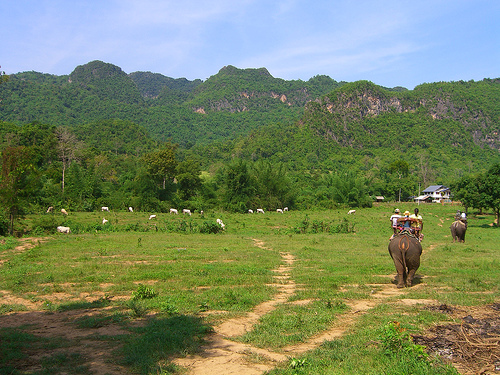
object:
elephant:
[388, 233, 423, 287]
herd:
[54, 226, 70, 234]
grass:
[2, 200, 500, 373]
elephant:
[450, 220, 467, 244]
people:
[459, 211, 467, 220]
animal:
[168, 208, 179, 215]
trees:
[3, 134, 46, 213]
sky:
[1, 0, 499, 90]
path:
[208, 234, 301, 339]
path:
[278, 238, 447, 357]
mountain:
[3, 60, 499, 145]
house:
[414, 183, 452, 204]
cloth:
[392, 229, 421, 239]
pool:
[449, 314, 500, 375]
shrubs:
[325, 217, 355, 231]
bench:
[392, 217, 421, 233]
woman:
[410, 207, 422, 219]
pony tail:
[415, 210, 418, 216]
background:
[3, 0, 496, 210]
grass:
[110, 313, 214, 367]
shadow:
[467, 222, 495, 229]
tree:
[476, 159, 500, 229]